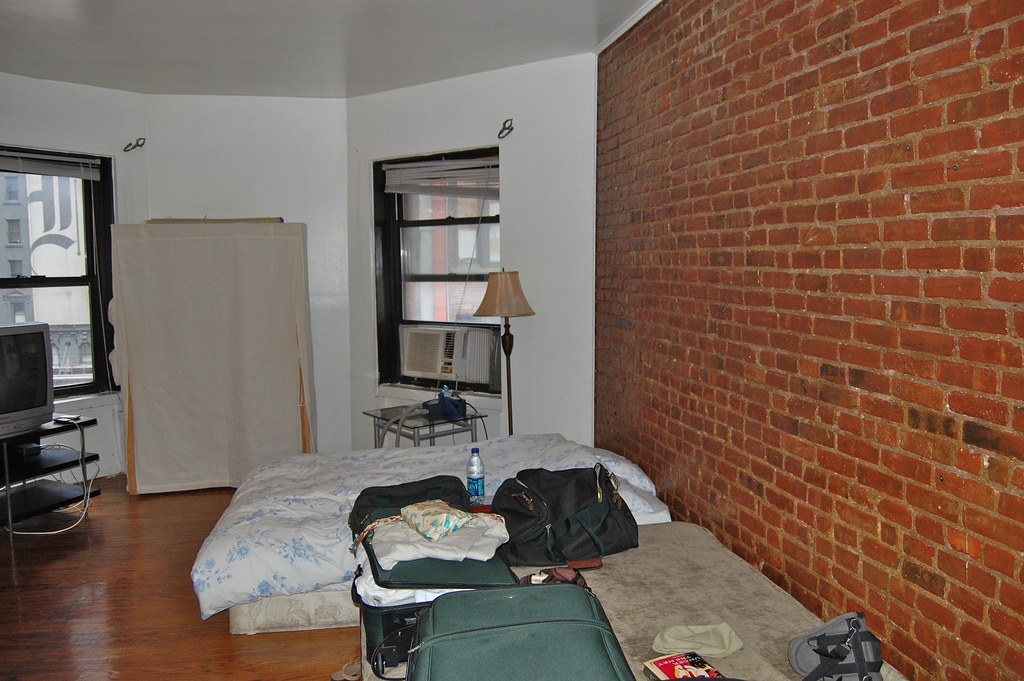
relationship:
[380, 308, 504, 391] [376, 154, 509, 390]
air conditioner in window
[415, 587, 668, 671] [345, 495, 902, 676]
luggage on bed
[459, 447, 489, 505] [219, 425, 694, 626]
water bottle by bed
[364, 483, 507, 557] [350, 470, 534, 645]
clothes on luggage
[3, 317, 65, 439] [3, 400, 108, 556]
tv on stand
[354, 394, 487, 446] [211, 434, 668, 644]
table on bed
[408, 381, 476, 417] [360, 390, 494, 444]
phone on table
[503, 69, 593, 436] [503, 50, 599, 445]
wall in wall